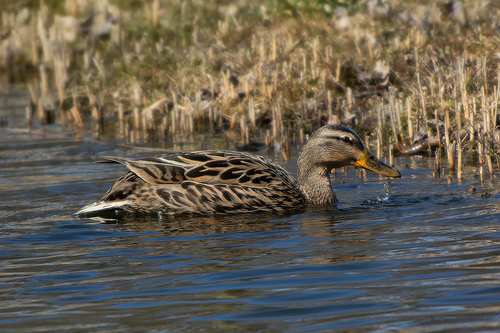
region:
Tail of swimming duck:
[63, 195, 141, 223]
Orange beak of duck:
[351, 151, 396, 178]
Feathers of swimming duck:
[136, 151, 198, 181]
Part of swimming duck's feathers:
[212, 153, 256, 175]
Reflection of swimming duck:
[160, 218, 267, 239]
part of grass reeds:
[398, 102, 485, 159]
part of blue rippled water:
[8, 160, 73, 220]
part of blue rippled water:
[134, 292, 268, 328]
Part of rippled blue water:
[428, 245, 485, 307]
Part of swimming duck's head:
[298, 165, 328, 205]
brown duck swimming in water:
[77, 122, 402, 224]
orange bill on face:
[352, 148, 404, 179]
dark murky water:
[7, 116, 498, 329]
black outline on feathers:
[186, 155, 283, 190]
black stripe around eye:
[317, 133, 361, 148]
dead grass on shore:
[107, 17, 499, 164]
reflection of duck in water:
[126, 208, 374, 244]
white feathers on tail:
[65, 200, 120, 222]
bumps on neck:
[316, 168, 333, 193]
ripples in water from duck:
[131, 268, 478, 331]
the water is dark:
[25, 250, 470, 322]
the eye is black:
[340, 126, 355, 148]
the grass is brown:
[410, 61, 485, 147]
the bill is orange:
[350, 145, 402, 180]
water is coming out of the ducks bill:
[362, 148, 410, 211]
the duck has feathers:
[155, 157, 294, 219]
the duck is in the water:
[45, 80, 433, 267]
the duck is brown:
[66, 127, 431, 240]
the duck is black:
[39, 122, 422, 250]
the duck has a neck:
[302, 156, 328, 193]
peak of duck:
[341, 141, 401, 186]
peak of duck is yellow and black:
[350, 150, 405, 180]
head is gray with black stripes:
[300, 115, 365, 170]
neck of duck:
[285, 155, 340, 210]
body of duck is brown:
[70, 135, 305, 225]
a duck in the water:
[0, 105, 496, 325]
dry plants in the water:
[8, 7, 498, 156]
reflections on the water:
[86, 219, 443, 284]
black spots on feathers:
[78, 138, 300, 213]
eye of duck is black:
[336, 129, 353, 148]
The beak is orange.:
[350, 151, 402, 185]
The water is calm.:
[7, 94, 489, 331]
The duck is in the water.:
[83, 106, 395, 244]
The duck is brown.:
[73, 106, 407, 248]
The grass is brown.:
[8, 9, 494, 181]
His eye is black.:
[335, 132, 357, 148]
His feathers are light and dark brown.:
[69, 133, 299, 213]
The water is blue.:
[12, 110, 497, 331]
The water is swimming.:
[55, 119, 413, 232]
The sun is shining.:
[7, 9, 489, 330]